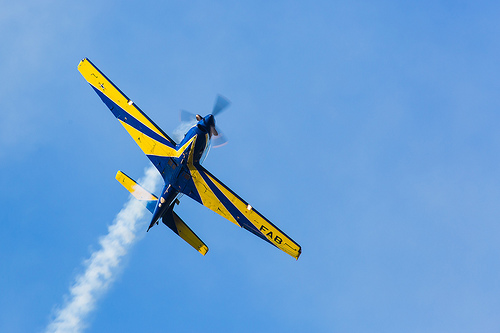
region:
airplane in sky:
[55, 42, 322, 288]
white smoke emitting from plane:
[50, 158, 166, 329]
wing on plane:
[199, 169, 326, 262]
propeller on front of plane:
[166, 88, 253, 153]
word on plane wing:
[255, 220, 292, 250]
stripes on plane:
[189, 167, 319, 261]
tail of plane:
[112, 169, 226, 286]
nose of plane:
[190, 98, 227, 140]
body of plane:
[142, 108, 210, 249]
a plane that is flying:
[68, 45, 284, 287]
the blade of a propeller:
[187, 79, 225, 116]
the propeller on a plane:
[186, 79, 236, 147]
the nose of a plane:
[180, 105, 233, 140]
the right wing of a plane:
[62, 54, 162, 154]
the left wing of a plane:
[192, 152, 304, 257]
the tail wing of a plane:
[107, 172, 207, 266]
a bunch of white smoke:
[72, 230, 134, 297]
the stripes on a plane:
[125, 97, 165, 162]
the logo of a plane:
[249, 212, 288, 254]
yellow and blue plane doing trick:
[52, 42, 316, 294]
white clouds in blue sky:
[262, 52, 339, 112]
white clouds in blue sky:
[220, 19, 257, 34]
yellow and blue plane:
[60, 56, 310, 268]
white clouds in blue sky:
[387, 96, 452, 158]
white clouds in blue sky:
[322, 156, 389, 231]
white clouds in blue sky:
[377, 229, 431, 303]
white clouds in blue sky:
[264, 285, 318, 332]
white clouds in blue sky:
[205, 265, 257, 320]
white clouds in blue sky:
[150, 276, 218, 331]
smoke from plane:
[61, 249, 125, 294]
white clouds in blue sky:
[257, 6, 319, 63]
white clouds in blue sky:
[371, 135, 435, 206]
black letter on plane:
[256, 223, 268, 235]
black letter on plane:
[263, 229, 274, 238]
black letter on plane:
[270, 232, 281, 244]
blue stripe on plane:
[195, 166, 270, 242]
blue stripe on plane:
[145, 143, 202, 230]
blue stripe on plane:
[88, 86, 171, 149]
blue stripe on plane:
[142, 197, 157, 212]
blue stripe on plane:
[162, 205, 176, 237]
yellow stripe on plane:
[191, 139, 231, 231]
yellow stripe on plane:
[115, 119, 192, 157]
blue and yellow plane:
[57, 43, 318, 281]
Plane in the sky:
[59, 55, 317, 291]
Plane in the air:
[56, 50, 310, 278]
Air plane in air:
[66, 53, 311, 285]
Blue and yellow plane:
[61, 50, 328, 289]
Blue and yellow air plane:
[66, 55, 332, 289]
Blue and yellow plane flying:
[37, 48, 327, 295]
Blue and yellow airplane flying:
[68, 50, 331, 280]